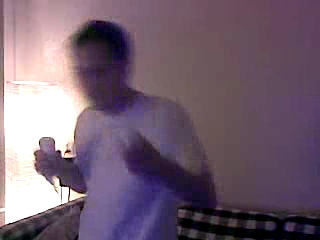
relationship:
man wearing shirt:
[33, 18, 223, 240] [74, 92, 207, 239]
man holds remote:
[33, 18, 223, 240] [34, 135, 58, 179]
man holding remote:
[33, 18, 223, 240] [34, 135, 58, 179]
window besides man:
[4, 3, 64, 91] [33, 18, 223, 240]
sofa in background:
[1, 196, 318, 237] [1, 118, 316, 232]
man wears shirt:
[33, 18, 223, 240] [74, 92, 207, 239]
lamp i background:
[50, 95, 74, 151] [1, 118, 316, 232]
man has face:
[33, 18, 223, 240] [78, 45, 109, 99]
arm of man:
[106, 129, 219, 209] [33, 18, 223, 240]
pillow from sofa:
[169, 209, 283, 239] [1, 196, 318, 237]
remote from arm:
[34, 135, 58, 179] [106, 129, 219, 209]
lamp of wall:
[50, 95, 74, 151] [224, 5, 317, 206]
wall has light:
[224, 5, 317, 206] [4, 87, 84, 216]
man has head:
[33, 18, 223, 240] [62, 17, 138, 111]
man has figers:
[33, 18, 223, 240] [124, 142, 141, 176]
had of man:
[127, 141, 158, 174] [33, 18, 223, 240]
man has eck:
[33, 18, 223, 240] [97, 86, 133, 108]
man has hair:
[33, 18, 223, 240] [87, 20, 141, 66]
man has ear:
[33, 18, 223, 240] [113, 59, 136, 81]